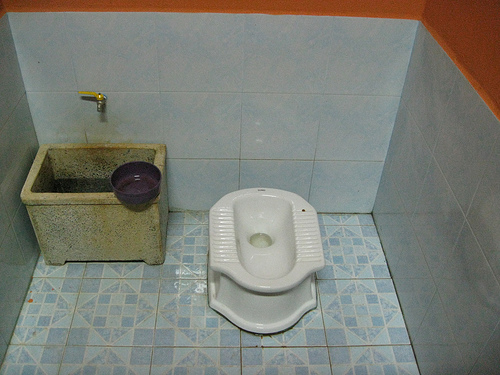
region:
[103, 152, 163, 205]
The bowl on the ledge of the sink basin.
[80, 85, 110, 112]
The faucet mounted on the wall.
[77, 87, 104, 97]
The yellow faucet handle.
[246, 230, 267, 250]
The hole inside of the toilet.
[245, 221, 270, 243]
The water in the toilet around the hole.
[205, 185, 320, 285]
The top of the toilet.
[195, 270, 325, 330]
The bottom of the toilet.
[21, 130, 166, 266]
The basin of the water tank on the left.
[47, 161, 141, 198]
The water inside of the sink basin.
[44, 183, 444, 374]
The blue and white tiles on the floor.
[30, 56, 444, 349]
Toilet in another country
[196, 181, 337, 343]
Toilet is white porcelain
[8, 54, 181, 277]
Sink with purple bowl sitting on side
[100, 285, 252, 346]
Blue linoleum on floor of restroom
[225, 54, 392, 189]
Porcelain tiled walls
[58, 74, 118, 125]
Water spigot on wall of restroom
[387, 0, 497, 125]
Orange painted walls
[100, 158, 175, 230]
Purple bowl for rinsing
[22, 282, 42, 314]
Splatter of orange paint on floor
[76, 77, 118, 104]
Yellow handle on spigot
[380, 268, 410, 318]
edge of a wall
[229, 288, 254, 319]
part of a toilet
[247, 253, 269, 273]
part of a floor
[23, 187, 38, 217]
part of a tank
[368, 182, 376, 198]
edge of a wall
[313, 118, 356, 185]
side of a wall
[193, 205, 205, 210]
edge of a wall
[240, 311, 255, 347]
bottom of a toilet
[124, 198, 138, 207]
edge of a tank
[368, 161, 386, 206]
corner of a tile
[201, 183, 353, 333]
A small toilet close to the ground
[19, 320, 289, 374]
The light blue tile floor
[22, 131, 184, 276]
A very dirty white sink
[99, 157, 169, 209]
A purple bowl on top of the dirty sink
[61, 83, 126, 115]
The faucet that pours out the water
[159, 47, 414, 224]
The tile against the back of the sink and toilet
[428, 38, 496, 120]
Orange wall paint color on the wall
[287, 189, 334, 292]
Right side of the toilet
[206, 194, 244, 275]
left side of the table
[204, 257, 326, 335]
The front of the toilet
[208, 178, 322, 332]
a very small ceramic white toilet bowl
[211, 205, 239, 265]
a line of ridges on the side of the toilet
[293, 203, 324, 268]
a line of ridges on the side of the toilet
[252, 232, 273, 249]
the drain of the toilet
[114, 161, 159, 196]
a small dark blue bowl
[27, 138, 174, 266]
a dirty concrete rectangle sink on the floor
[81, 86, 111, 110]
a silver faucet on the wall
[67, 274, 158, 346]
a light blue and dark blue tile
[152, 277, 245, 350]
a light blue and dark blue tile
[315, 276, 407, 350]
a light blue and dark blue tile